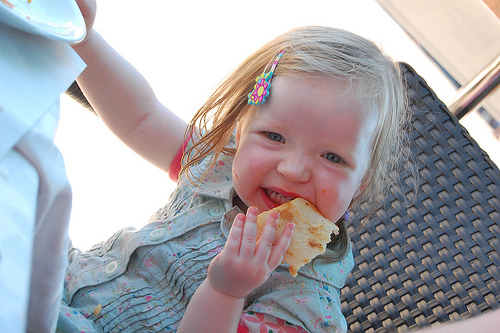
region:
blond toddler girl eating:
[95, 15, 467, 310]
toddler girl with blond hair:
[156, 16, 416, 231]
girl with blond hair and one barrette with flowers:
[212, 16, 297, 117]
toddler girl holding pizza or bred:
[73, 174, 388, 326]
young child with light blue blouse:
[1, 181, 336, 324]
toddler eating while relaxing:
[261, 26, 482, 308]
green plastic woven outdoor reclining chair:
[391, 150, 472, 290]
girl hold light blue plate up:
[2, 0, 149, 96]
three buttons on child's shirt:
[95, 182, 225, 301]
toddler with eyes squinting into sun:
[219, 101, 421, 211]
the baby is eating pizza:
[228, 200, 356, 278]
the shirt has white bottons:
[103, 211, 201, 283]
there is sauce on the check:
[303, 185, 353, 212]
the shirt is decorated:
[141, 231, 192, 321]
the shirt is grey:
[92, 232, 177, 284]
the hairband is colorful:
[244, 65, 289, 129]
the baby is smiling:
[240, 105, 355, 210]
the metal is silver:
[451, 65, 491, 120]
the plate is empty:
[0, 0, 95, 47]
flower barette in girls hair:
[246, 45, 274, 114]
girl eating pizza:
[256, 190, 342, 303]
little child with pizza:
[217, 44, 366, 273]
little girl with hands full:
[153, 50, 411, 331]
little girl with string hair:
[177, 18, 424, 278]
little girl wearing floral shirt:
[80, 130, 345, 325]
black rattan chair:
[380, 195, 472, 302]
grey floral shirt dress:
[238, 289, 347, 324]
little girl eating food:
[225, 156, 342, 294]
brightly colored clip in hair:
[242, 36, 297, 118]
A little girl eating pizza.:
[249, 183, 361, 301]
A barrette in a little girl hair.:
[245, 27, 310, 109]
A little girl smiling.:
[233, 46, 402, 258]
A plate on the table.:
[6, 7, 101, 67]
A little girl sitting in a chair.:
[99, 86, 494, 302]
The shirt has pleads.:
[96, 224, 218, 311]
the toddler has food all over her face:
[240, 155, 343, 222]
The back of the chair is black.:
[371, 75, 471, 311]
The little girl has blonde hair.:
[238, 33, 403, 223]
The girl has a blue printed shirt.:
[79, 204, 254, 331]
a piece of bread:
[238, 194, 338, 276]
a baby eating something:
[69, 0, 412, 329]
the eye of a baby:
[256, 127, 290, 148]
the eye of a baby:
[324, 147, 349, 167]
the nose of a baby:
[276, 158, 310, 187]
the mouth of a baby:
[255, 178, 316, 220]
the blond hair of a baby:
[178, 21, 416, 239]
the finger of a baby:
[226, 210, 241, 252]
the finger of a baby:
[258, 211, 278, 261]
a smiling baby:
[54, 0, 414, 330]